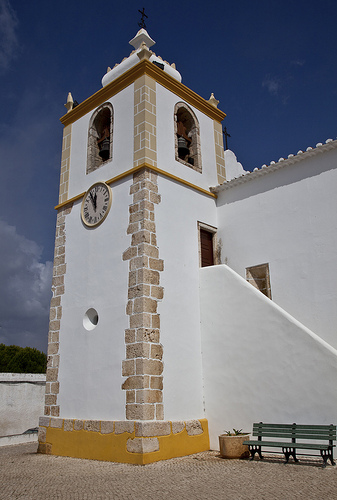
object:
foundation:
[40, 419, 214, 466]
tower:
[46, 8, 233, 424]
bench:
[244, 419, 335, 467]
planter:
[217, 428, 251, 459]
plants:
[226, 429, 247, 437]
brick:
[129, 79, 157, 431]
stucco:
[68, 230, 126, 415]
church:
[34, 7, 337, 464]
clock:
[77, 181, 113, 231]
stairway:
[204, 260, 336, 459]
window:
[81, 103, 115, 178]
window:
[173, 99, 207, 176]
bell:
[96, 131, 113, 156]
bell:
[178, 123, 190, 151]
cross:
[134, 4, 152, 32]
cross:
[220, 124, 234, 154]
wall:
[220, 165, 335, 319]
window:
[80, 307, 100, 332]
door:
[200, 226, 217, 269]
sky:
[0, 2, 336, 130]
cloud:
[6, 225, 50, 326]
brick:
[39, 415, 202, 437]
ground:
[75, 462, 334, 498]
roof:
[211, 136, 335, 196]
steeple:
[96, 28, 186, 77]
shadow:
[248, 455, 330, 470]